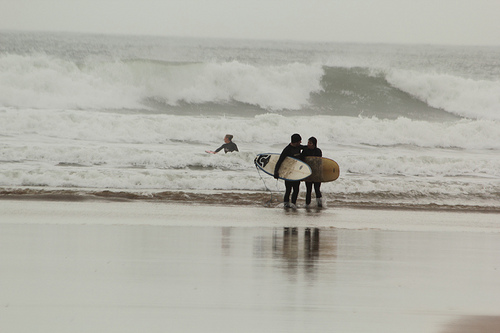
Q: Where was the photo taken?
A: At the beach.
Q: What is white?
A: The waves.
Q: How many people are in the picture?
A: Three.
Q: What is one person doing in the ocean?
A: Surfing.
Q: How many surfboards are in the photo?
A: Two.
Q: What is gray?
A: The sky.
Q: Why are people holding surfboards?
A: To surf.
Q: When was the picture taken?
A: On a cloudy day.